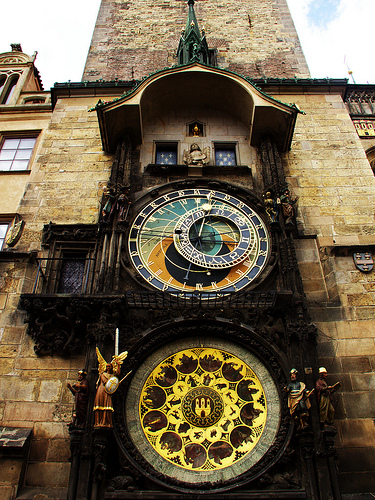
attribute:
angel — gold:
[178, 138, 212, 170]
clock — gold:
[141, 343, 274, 466]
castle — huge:
[43, 32, 286, 276]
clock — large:
[123, 183, 279, 303]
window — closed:
[1, 126, 41, 176]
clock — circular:
[123, 173, 275, 312]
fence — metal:
[30, 255, 102, 293]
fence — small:
[34, 260, 88, 293]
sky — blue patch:
[308, 4, 344, 31]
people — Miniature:
[84, 344, 133, 427]